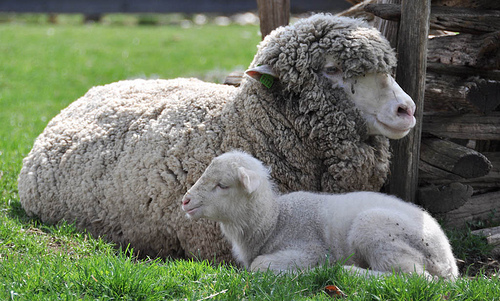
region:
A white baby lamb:
[178, 142, 465, 293]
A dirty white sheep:
[19, 4, 406, 245]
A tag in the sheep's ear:
[251, 70, 284, 94]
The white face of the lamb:
[315, 12, 433, 147]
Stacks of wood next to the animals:
[431, 12, 498, 210]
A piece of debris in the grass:
[309, 276, 374, 298]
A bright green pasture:
[3, 22, 118, 84]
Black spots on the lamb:
[386, 212, 440, 274]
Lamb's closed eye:
[201, 160, 241, 198]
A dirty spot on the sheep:
[342, 82, 358, 102]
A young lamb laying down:
[178, 148, 463, 286]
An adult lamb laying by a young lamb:
[19, 12, 466, 286]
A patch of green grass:
[5, 227, 87, 297]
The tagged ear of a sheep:
[237, 57, 294, 94]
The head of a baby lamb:
[181, 148, 277, 232]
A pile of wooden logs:
[395, 10, 498, 239]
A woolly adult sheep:
[66, 17, 416, 196]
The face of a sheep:
[314, 38, 422, 141]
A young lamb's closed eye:
[194, 163, 241, 203]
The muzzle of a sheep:
[367, 91, 417, 142]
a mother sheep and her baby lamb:
[18, 12, 459, 285]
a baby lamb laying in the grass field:
[183, 150, 461, 289]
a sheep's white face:
[322, 61, 416, 138]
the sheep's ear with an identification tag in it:
[245, 67, 281, 92]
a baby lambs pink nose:
[181, 193, 191, 206]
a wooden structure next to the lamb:
[416, 1, 499, 272]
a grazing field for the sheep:
[1, 13, 259, 77]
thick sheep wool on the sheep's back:
[18, 78, 183, 251]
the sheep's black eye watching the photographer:
[323, 62, 338, 77]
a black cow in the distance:
[76, 8, 106, 25]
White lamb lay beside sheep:
[175, 146, 455, 282]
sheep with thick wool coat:
[38, 11, 415, 259]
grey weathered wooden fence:
[403, 3, 498, 253]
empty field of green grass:
[15, 28, 262, 84]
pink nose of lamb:
[175, 191, 202, 213]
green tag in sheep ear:
[254, 68, 291, 88]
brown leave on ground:
[312, 283, 351, 296]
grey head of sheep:
[278, 24, 440, 158]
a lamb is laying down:
[174, 149, 471, 287]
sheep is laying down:
[49, 25, 431, 254]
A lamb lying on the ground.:
[137, 149, 482, 291]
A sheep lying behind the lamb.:
[31, 0, 451, 237]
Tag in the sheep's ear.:
[236, 52, 286, 101]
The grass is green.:
[20, 45, 90, 78]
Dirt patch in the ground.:
[10, 212, 87, 277]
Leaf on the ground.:
[286, 270, 397, 299]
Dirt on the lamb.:
[361, 206, 455, 278]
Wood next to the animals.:
[267, 5, 499, 253]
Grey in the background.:
[8, 2, 267, 27]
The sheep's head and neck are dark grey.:
[243, 22, 409, 184]